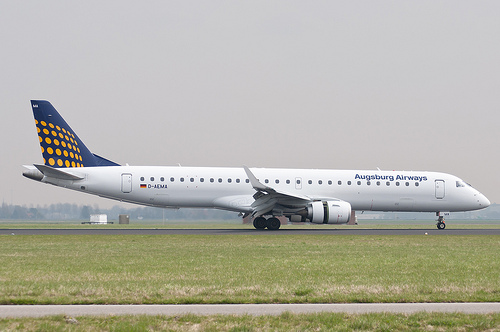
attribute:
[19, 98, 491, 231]
plane — here, big, white, yel, blue,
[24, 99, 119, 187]
tail — sharp, blue, yellow, blue with yellow dot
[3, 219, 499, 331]
grass — here, green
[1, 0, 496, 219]
sky — grey, hazy, overcast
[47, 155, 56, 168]
dot — yellow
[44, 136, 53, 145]
dot — yellow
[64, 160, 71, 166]
dot — yellow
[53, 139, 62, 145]
dot — yellow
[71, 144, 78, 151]
dot — yellow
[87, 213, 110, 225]
structure — white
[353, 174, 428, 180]
augsburg airways — blue